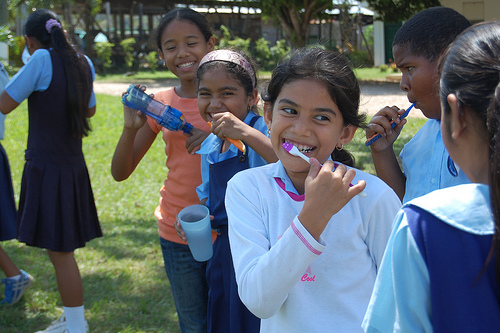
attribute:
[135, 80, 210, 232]
shirt — orange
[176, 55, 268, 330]
child — small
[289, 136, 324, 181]
toothbrushes — purple, white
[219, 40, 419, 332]
child — small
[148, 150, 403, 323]
sweater — white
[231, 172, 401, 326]
sweater — white, pink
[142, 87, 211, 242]
shirt — orange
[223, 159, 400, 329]
shirt — pink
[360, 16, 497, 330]
child — small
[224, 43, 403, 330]
child — small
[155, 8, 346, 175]
children — smiling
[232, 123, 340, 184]
toothbrush — white, purple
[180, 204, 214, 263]
cup — blue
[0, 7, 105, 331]
child — small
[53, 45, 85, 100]
hair — long